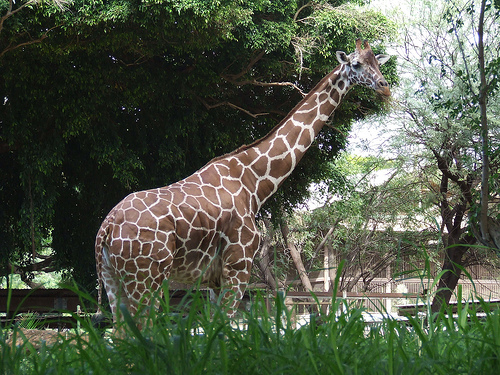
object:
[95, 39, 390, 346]
giraffe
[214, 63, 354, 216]
neck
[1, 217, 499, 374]
grass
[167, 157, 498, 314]
building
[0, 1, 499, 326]
background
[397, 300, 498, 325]
bench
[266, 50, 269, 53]
leaf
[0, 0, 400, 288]
tree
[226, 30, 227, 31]
leaf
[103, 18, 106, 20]
leaf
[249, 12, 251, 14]
leaf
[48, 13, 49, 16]
leaf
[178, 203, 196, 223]
patch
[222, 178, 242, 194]
patch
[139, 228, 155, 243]
patch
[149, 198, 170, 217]
patch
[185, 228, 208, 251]
patch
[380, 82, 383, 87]
nostril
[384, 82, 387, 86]
nostril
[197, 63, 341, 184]
mane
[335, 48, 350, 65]
ear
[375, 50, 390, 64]
ear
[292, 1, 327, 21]
branch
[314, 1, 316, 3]
leaf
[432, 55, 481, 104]
branch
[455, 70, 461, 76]
leaf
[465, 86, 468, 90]
leaf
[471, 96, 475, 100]
leaf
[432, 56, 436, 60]
leaf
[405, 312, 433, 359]
blade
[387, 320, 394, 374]
blade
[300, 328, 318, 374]
blade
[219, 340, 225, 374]
blade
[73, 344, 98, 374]
blade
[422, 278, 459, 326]
trunk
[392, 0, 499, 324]
tree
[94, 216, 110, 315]
tail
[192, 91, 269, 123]
branch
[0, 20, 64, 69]
branch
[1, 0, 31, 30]
branch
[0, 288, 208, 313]
wall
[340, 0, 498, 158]
sky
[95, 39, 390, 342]
skin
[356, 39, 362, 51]
horn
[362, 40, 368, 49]
horn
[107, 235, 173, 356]
behind leg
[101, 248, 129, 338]
behind leg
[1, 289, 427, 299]
railing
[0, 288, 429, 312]
fence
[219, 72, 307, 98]
branch